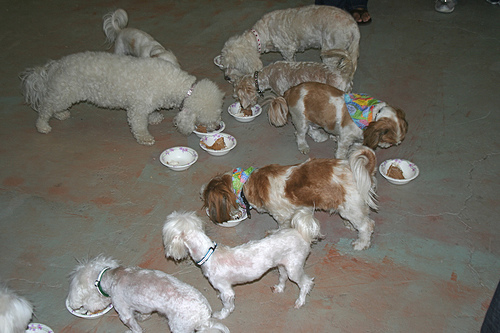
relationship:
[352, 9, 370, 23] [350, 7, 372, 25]
foot wearing sandal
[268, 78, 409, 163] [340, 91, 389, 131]
pet wearing scarf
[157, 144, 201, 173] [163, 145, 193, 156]
dish has purple flowers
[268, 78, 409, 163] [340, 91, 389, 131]
pet has on scarf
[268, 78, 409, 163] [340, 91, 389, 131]
pet with scarf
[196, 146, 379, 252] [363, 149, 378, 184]
pet has spot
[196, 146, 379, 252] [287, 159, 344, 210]
pet has spot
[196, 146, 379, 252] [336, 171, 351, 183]
pet has spot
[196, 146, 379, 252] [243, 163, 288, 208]
pet has spot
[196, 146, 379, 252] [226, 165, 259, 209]
pet wearing bandana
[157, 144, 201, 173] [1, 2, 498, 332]
dish on floor